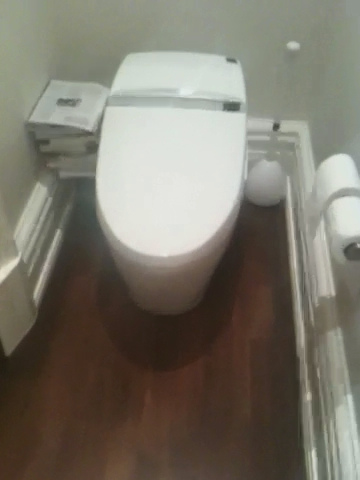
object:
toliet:
[94, 51, 246, 318]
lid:
[93, 106, 248, 271]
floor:
[0, 199, 305, 479]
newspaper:
[27, 79, 110, 133]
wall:
[0, 1, 359, 437]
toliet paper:
[302, 152, 360, 272]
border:
[0, 116, 359, 479]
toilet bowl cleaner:
[243, 35, 299, 208]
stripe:
[106, 96, 245, 112]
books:
[43, 141, 96, 181]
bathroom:
[0, 2, 359, 478]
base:
[245, 158, 286, 207]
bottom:
[107, 241, 223, 321]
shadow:
[96, 260, 236, 376]